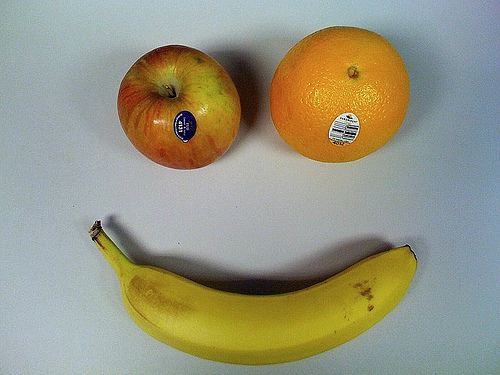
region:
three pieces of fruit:
[72, 42, 464, 358]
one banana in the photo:
[59, 220, 434, 373]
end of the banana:
[357, 228, 439, 303]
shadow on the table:
[202, 234, 292, 293]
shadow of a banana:
[255, 217, 375, 272]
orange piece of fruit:
[266, 20, 438, 173]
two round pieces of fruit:
[86, 35, 428, 176]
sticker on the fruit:
[300, 97, 377, 173]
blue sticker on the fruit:
[158, 103, 212, 155]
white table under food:
[226, 171, 293, 221]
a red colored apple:
[116, 34, 238, 171]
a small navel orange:
[268, 29, 410, 163]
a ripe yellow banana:
[76, 206, 433, 368]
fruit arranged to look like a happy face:
[58, 33, 479, 359]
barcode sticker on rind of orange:
[315, 103, 367, 153]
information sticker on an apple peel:
[162, 108, 201, 145]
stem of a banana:
[86, 221, 128, 275]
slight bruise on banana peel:
[350, 275, 382, 317]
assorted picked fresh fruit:
[89, 51, 461, 370]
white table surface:
[213, 183, 300, 242]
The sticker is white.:
[323, 109, 361, 146]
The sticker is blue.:
[174, 106, 196, 146]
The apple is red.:
[100, 34, 240, 169]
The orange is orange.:
[261, 20, 404, 166]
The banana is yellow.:
[85, 220, 470, 356]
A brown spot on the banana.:
[355, 278, 382, 317]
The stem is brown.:
[75, 213, 126, 270]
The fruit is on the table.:
[70, 31, 439, 368]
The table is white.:
[1, 5, 498, 356]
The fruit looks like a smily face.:
[78, 32, 421, 360]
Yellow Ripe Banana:
[80, 217, 417, 365]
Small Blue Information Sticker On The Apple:
[173, 110, 195, 142]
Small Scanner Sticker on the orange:
[327, 111, 358, 146]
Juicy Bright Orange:
[266, 26, 410, 166]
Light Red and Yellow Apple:
[115, 41, 238, 172]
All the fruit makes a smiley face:
[88, 21, 422, 371]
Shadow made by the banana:
[100, 210, 388, 298]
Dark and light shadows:
[202, 25, 289, 156]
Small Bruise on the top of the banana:
[128, 271, 190, 328]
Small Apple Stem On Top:
[160, 78, 180, 101]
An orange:
[267, 23, 412, 168]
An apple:
[112, 43, 244, 176]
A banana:
[83, 217, 421, 367]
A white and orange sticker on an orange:
[327, 106, 359, 151]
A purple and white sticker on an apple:
[173, 106, 198, 144]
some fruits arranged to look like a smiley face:
[87, 22, 420, 367]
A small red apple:
[113, 38, 244, 175]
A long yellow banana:
[89, 219, 414, 365]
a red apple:
[114, 39, 241, 171]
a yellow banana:
[88, 218, 425, 362]